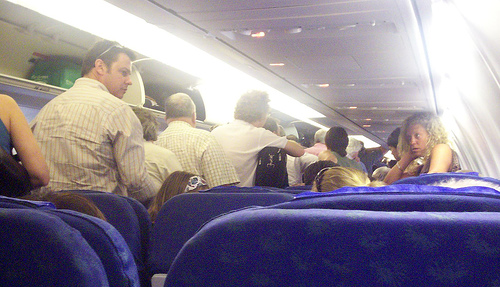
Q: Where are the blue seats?
A: On the airplane.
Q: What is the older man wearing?
A: A checkered shirt.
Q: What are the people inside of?
A: An airplane.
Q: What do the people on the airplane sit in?
A: Seats.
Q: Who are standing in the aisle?
A: Passengers.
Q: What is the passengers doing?
A: Standing.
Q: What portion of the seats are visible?
A: The back.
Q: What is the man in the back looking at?
A: The woman.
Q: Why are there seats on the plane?
A: For sitting.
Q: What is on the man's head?
A: Glasses.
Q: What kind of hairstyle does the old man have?
A: Balding.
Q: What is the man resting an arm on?
A: A suitcase.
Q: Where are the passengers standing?
A: An airplane.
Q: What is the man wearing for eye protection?
A: Sunglasses.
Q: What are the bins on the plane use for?
A: Storage.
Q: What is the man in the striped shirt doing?
A: Looking over the right shoulder.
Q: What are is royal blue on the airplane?
A: The seats.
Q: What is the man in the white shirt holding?
A: Luggage.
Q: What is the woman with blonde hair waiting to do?
A: Leave her seat.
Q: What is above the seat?
A: Cargo space.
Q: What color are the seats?
A: Blue.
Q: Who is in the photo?
A: People.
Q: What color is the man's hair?
A: Brown.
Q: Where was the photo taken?
A: In airplane.